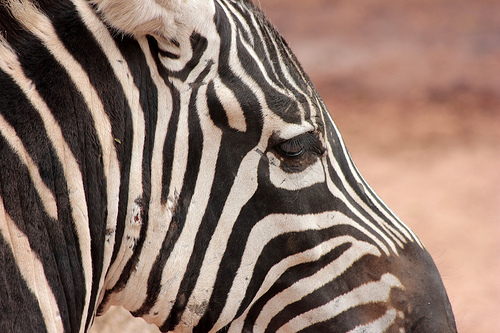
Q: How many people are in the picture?
A: None.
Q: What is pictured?
A: A zebra.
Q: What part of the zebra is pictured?
A: The head.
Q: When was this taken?
A: During the day.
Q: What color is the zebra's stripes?
A: Black.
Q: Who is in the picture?
A: No one.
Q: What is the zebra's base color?
A: White.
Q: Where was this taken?
A: In the field.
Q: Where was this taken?
A: At the safari.